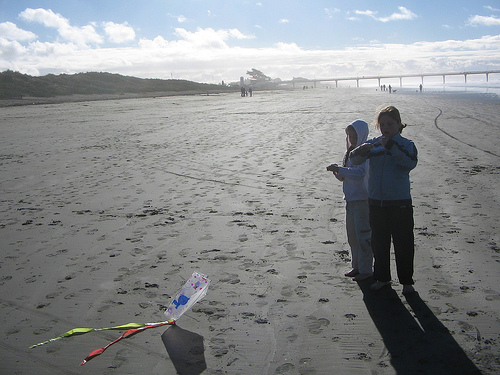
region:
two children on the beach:
[332, 93, 423, 300]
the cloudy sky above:
[6, 6, 484, 81]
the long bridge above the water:
[253, 72, 496, 93]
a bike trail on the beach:
[417, 100, 493, 207]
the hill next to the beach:
[0, 62, 238, 97]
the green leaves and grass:
[2, 66, 58, 96]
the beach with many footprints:
[10, 96, 492, 371]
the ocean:
[408, 80, 494, 107]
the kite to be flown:
[47, 260, 212, 372]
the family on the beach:
[236, 84, 255, 100]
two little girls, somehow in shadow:
[324, 104, 428, 299]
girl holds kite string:
[346, 132, 422, 177]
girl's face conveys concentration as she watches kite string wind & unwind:
[376, 117, 399, 141]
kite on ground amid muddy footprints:
[13, 255, 237, 373]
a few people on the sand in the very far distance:
[200, 82, 433, 101]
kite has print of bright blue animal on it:
[170, 290, 191, 310]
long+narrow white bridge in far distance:
[266, 68, 498, 92]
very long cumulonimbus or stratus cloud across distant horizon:
[0, 45, 499, 72]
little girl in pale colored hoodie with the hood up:
[331, 118, 373, 200]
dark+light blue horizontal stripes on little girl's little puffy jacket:
[364, 139, 409, 160]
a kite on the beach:
[41, 275, 231, 369]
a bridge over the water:
[294, 75, 499, 87]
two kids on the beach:
[324, 110, 419, 276]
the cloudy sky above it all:
[123, 36, 490, 69]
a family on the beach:
[233, 85, 253, 98]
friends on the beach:
[375, 79, 395, 95]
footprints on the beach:
[48, 138, 294, 284]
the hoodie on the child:
[331, 123, 373, 211]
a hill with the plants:
[6, 67, 178, 104]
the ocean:
[431, 80, 498, 99]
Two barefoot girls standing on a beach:
[326, 110, 416, 283]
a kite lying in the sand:
[31, 270, 221, 355]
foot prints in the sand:
[225, 226, 291, 296]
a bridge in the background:
[292, 65, 497, 85]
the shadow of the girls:
[361, 296, 468, 372]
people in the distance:
[236, 83, 259, 100]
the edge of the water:
[456, 78, 498, 103]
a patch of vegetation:
[5, 68, 168, 98]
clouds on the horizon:
[15, 8, 430, 71]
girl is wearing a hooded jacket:
[339, 118, 368, 204]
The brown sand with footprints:
[101, 134, 236, 209]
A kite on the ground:
[51, 276, 228, 356]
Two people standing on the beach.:
[323, 124, 441, 253]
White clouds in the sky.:
[97, 8, 322, 53]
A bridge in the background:
[333, 66, 472, 104]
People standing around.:
[223, 82, 408, 113]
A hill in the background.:
[6, 76, 138, 126]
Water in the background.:
[465, 83, 499, 98]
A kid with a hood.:
[315, 131, 370, 248]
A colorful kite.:
[72, 276, 216, 358]